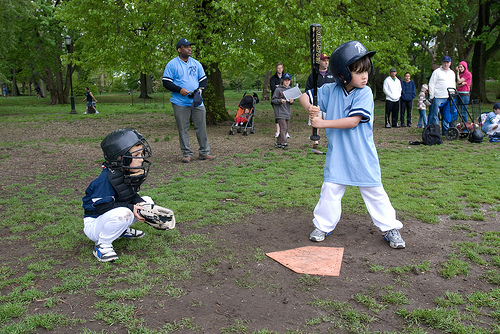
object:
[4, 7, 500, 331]
game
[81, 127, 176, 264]
kid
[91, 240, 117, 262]
blue shoe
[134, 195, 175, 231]
catchers mitt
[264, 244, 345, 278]
homeplate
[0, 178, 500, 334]
ground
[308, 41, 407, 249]
boy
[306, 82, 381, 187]
shirt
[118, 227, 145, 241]
shoe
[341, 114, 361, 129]
left elbow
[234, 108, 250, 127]
child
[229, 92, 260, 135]
stroller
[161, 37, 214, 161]
man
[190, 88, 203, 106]
mitt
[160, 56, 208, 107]
blue shirt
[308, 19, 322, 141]
baseball bat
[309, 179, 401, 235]
white pants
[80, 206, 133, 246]
white pants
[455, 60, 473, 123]
lady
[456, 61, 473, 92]
pink shirt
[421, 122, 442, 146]
backpack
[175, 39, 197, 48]
hat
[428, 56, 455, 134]
guy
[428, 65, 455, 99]
white shirt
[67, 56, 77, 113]
post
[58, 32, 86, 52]
light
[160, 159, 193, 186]
patches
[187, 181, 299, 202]
grass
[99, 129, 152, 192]
catchers mask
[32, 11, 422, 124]
tree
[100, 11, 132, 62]
green leaves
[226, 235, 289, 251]
dirt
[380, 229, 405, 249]
foot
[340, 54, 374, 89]
head